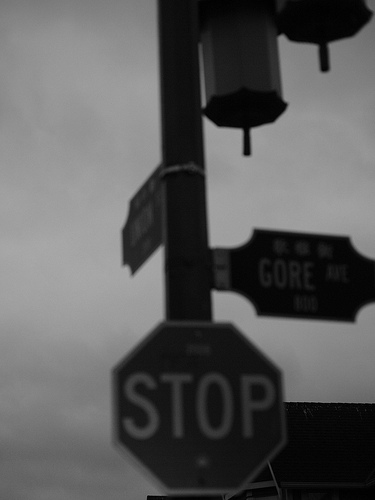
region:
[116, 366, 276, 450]
the sign reads STOP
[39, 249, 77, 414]
the sky is dreary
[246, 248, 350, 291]
the sign reads gore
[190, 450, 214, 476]
the sign has a screw in it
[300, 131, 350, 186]
the sky is gloomy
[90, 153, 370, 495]
the signs are on top of one another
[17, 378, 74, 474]
the sky is white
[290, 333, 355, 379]
the sky is cloudy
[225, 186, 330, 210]
the sky is gray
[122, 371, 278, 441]
STOP is white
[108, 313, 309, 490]
stop sign with white letters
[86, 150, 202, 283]
road sign at an angle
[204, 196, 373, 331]
road sign saying Gore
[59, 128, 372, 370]
two road signs at an intersection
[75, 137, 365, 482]
two street signs and a stop sign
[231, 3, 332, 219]
lamp hanging in the air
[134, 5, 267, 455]
pole holding up the stop sign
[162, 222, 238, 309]
hinge connecting the street sign to the pole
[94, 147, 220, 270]
hinge connecting the street sign to the pole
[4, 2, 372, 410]
black and white photo of a street sign and pole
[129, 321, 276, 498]
black and white stop sign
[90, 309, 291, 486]
stop sign is octagonal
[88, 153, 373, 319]
two street signs above stop sign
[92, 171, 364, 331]
signs are perpendicular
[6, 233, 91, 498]
sky is cloudy and grey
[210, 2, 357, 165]
two objects above street signs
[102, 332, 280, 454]
stop sign below street signs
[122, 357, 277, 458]
letters on sign are white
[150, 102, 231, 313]
stop sign on pole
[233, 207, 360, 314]
decorative street sign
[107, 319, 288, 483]
stop sign in a pole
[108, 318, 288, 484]
octahedron stop sign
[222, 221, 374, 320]
gore street sign in a pole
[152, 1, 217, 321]
black large pole with signs on it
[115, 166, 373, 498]
three signs in a black large pole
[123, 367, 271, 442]
white stop letters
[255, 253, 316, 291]
white gore letters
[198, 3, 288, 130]
part of the lights in a pole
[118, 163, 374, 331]
two signs with the same shape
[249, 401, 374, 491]
part of a roof of a house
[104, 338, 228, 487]
a stop sign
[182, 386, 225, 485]
a stop sign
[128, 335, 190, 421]
a stop sign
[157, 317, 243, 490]
a stop sign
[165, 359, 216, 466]
a stop sign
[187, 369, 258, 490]
a stop sign